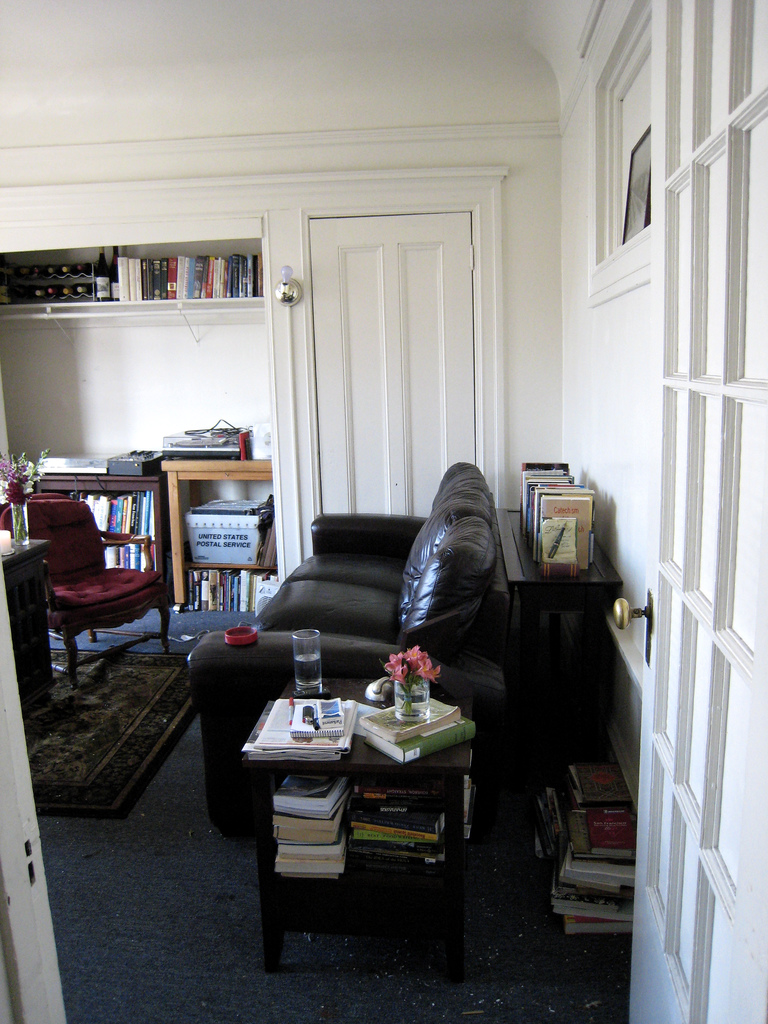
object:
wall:
[1, 0, 766, 806]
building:
[0, 0, 765, 1013]